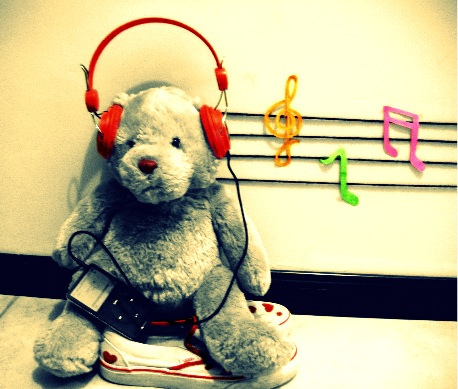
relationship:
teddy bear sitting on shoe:
[34, 87, 295, 381] [146, 301, 292, 340]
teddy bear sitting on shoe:
[34, 87, 295, 381] [99, 328, 300, 388]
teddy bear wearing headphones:
[34, 87, 295, 381] [79, 16, 232, 162]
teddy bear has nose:
[34, 87, 295, 381] [137, 158, 158, 175]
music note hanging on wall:
[319, 148, 359, 206] [0, 0, 457, 279]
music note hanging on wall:
[382, 103, 426, 172] [0, 0, 457, 279]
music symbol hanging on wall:
[261, 75, 304, 169] [0, 0, 457, 279]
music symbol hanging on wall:
[217, 112, 458, 189] [0, 0, 457, 279]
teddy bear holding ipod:
[34, 87, 295, 381] [67, 264, 158, 344]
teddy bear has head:
[34, 87, 295, 381] [106, 85, 222, 206]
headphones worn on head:
[79, 16, 232, 162] [106, 85, 222, 206]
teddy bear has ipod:
[34, 87, 295, 381] [67, 264, 158, 344]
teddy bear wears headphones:
[34, 87, 295, 381] [79, 16, 232, 162]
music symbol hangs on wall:
[217, 112, 458, 189] [0, 0, 457, 279]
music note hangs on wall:
[319, 148, 359, 206] [0, 0, 457, 279]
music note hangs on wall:
[382, 103, 426, 172] [0, 0, 457, 279]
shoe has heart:
[146, 301, 292, 340] [103, 350, 118, 364]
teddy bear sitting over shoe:
[34, 87, 295, 381] [146, 301, 292, 340]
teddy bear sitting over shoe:
[34, 87, 295, 381] [99, 328, 300, 388]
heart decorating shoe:
[103, 350, 118, 364] [99, 328, 300, 388]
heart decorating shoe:
[262, 300, 276, 313] [146, 301, 292, 340]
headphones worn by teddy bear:
[79, 16, 232, 162] [34, 87, 295, 381]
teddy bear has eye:
[34, 87, 295, 381] [125, 137, 137, 148]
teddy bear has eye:
[34, 87, 295, 381] [171, 137, 181, 148]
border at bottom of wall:
[1, 251, 457, 323] [0, 0, 457, 279]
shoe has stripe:
[99, 328, 300, 388] [97, 356, 243, 379]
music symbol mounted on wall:
[261, 75, 304, 169] [0, 0, 457, 279]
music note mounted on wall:
[319, 148, 359, 206] [0, 0, 457, 279]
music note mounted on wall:
[382, 103, 426, 172] [0, 0, 457, 279]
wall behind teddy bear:
[0, 0, 457, 279] [34, 87, 295, 381]